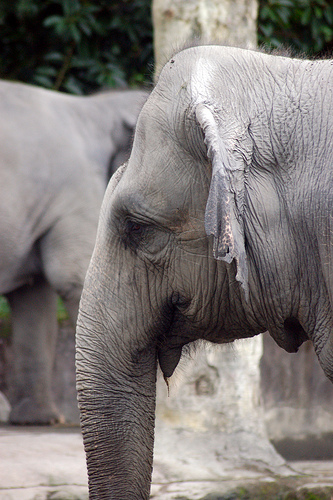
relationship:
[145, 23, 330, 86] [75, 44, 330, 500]
hair on elephant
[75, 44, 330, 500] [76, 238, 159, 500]
elephant has trunk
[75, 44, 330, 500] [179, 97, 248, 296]
elephant has ear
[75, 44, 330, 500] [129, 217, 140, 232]
elephant has eye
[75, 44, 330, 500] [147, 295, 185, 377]
elephant has mouth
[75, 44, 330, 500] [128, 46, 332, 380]
elephant has skin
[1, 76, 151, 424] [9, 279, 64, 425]
elephant has foot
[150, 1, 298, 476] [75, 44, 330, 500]
tree behind elephant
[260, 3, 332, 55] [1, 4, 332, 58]
leaves are on bush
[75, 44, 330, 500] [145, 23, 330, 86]
elephant has hair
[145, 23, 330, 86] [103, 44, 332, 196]
hair on head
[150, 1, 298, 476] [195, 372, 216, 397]
tree has knot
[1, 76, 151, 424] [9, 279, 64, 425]
elephant has leg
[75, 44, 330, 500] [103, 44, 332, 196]
elephant has head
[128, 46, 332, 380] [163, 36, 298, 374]
skin has wrinkles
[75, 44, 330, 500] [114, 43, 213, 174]
elephant has forehead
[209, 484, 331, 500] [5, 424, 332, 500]
grass on ground